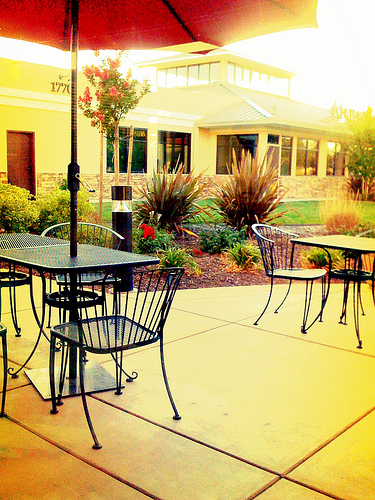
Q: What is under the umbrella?
A: A table and chairs.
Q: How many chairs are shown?
A: Four.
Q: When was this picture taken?
A: During the day.